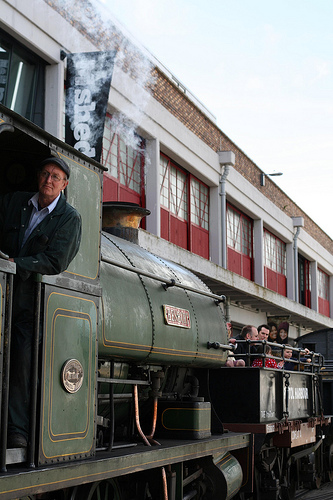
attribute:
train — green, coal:
[31, 274, 315, 454]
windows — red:
[172, 182, 217, 262]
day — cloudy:
[220, 17, 319, 140]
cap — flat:
[52, 156, 75, 170]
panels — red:
[160, 220, 216, 249]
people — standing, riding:
[251, 324, 297, 368]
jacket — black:
[6, 204, 77, 259]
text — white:
[288, 390, 316, 403]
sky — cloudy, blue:
[181, 10, 322, 132]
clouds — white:
[195, 37, 282, 79]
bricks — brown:
[152, 94, 201, 132]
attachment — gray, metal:
[57, 355, 95, 399]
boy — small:
[298, 347, 313, 368]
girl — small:
[256, 346, 284, 369]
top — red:
[259, 358, 273, 369]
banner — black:
[265, 316, 290, 343]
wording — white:
[283, 383, 316, 399]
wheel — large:
[303, 442, 330, 496]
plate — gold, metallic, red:
[161, 300, 197, 340]